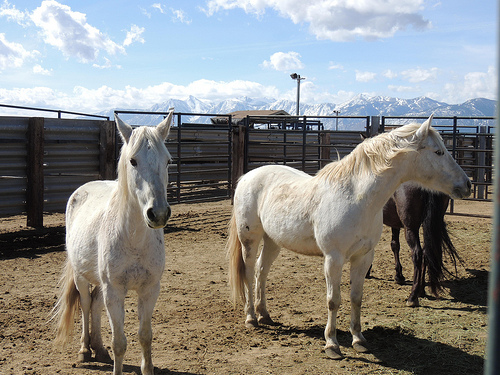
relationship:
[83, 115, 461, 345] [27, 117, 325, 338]
white horses in corral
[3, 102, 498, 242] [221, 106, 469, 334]
fence behind horse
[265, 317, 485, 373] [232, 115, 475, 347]
shadow of horse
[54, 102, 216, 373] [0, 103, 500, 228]
horse in fence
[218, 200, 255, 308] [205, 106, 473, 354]
tail of horse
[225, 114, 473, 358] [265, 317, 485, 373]
white horses casting shadow